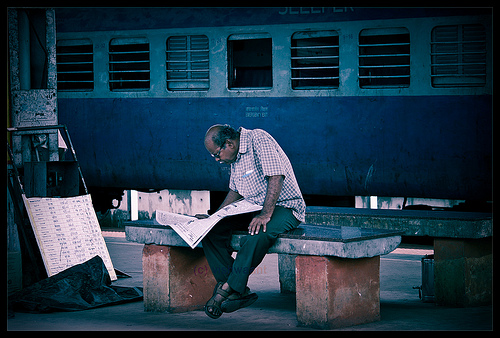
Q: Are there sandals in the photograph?
A: Yes, there are sandals.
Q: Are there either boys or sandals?
A: Yes, there are sandals.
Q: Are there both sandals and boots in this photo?
A: No, there are sandals but no boots.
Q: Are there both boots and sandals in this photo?
A: No, there are sandals but no boots.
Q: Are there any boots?
A: No, there are no boots.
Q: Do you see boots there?
A: No, there are no boots.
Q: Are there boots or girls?
A: No, there are no boots or girls.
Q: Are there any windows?
A: Yes, there is a window.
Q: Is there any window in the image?
A: Yes, there is a window.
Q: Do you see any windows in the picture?
A: Yes, there is a window.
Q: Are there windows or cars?
A: Yes, there is a window.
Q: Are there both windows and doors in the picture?
A: No, there is a window but no doors.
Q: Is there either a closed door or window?
A: Yes, there is a closed window.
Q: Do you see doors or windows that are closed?
A: Yes, the window is closed.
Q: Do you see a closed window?
A: Yes, there is a closed window.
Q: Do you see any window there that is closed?
A: Yes, there is a window that is closed.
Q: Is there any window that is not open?
A: Yes, there is an closed window.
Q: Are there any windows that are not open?
A: Yes, there is an closed window.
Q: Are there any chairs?
A: No, there are no chairs.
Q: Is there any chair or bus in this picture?
A: No, there are no chairs or buses.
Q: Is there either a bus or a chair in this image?
A: No, there are no chairs or buses.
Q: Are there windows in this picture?
A: Yes, there is a window.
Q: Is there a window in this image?
A: Yes, there is a window.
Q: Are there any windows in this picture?
A: Yes, there is a window.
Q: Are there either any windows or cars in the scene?
A: Yes, there is a window.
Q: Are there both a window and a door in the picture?
A: No, there is a window but no doors.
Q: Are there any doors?
A: No, there are no doors.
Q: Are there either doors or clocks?
A: No, there are no doors or clocks.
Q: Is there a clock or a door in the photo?
A: No, there are no doors or clocks.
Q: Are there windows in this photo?
A: Yes, there is a window.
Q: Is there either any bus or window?
A: Yes, there is a window.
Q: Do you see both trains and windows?
A: Yes, there are both a window and a train.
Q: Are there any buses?
A: No, there are no buses.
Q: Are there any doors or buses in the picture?
A: No, there are no buses or doors.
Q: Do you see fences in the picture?
A: No, there are no fences.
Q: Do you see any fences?
A: No, there are no fences.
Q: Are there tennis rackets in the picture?
A: No, there are no tennis rackets.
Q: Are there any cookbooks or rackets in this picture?
A: No, there are no rackets or cookbooks.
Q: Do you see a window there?
A: Yes, there is a window.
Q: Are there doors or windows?
A: Yes, there is a window.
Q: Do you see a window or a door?
A: Yes, there is a window.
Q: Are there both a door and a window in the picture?
A: No, there is a window but no doors.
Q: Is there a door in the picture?
A: No, there are no doors.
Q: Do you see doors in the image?
A: No, there are no doors.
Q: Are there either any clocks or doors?
A: No, there are no doors or clocks.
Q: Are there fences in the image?
A: No, there are no fences.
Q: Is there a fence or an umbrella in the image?
A: No, there are no fences or umbrellas.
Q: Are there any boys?
A: No, there are no boys.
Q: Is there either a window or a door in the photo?
A: Yes, there is a window.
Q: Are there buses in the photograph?
A: No, there are no buses.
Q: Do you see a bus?
A: No, there are no buses.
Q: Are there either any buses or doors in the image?
A: No, there are no buses or doors.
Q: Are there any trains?
A: Yes, there is a train.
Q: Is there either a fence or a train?
A: Yes, there is a train.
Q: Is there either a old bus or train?
A: Yes, there is an old train.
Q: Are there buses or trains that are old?
A: Yes, the train is old.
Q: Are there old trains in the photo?
A: Yes, there is an old train.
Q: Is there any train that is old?
A: Yes, there is a train that is old.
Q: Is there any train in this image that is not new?
A: Yes, there is a old train.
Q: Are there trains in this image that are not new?
A: Yes, there is a old train.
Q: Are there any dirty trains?
A: Yes, there is a dirty train.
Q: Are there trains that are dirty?
A: Yes, there is a train that is dirty.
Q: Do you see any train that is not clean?
A: Yes, there is a dirty train.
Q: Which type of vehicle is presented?
A: The vehicle is a train.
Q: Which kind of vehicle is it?
A: The vehicle is a train.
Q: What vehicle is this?
A: This is a train.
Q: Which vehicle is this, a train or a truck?
A: This is a train.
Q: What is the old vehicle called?
A: The vehicle is a train.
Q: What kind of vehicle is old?
A: The vehicle is a train.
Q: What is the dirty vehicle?
A: The vehicle is a train.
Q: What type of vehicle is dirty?
A: The vehicle is a train.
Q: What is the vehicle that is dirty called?
A: The vehicle is a train.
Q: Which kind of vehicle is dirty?
A: The vehicle is a train.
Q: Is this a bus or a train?
A: This is a train.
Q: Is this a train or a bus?
A: This is a train.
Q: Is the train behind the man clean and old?
A: No, the train is old but dirty.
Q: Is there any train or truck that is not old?
A: No, there is a train but it is old.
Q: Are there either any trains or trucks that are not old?
A: No, there is a train but it is old.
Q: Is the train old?
A: Yes, the train is old.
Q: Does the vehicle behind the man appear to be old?
A: Yes, the train is old.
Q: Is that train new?
A: No, the train is old.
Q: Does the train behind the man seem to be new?
A: No, the train is old.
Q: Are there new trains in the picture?
A: No, there is a train but it is old.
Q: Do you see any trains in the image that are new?
A: No, there is a train but it is old.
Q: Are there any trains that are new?
A: No, there is a train but it is old.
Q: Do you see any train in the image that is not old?
A: No, there is a train but it is old.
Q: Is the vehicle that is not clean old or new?
A: The train is old.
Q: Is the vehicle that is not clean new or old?
A: The train is old.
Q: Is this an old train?
A: Yes, this is an old train.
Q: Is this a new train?
A: No, this is an old train.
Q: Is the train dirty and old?
A: Yes, the train is dirty and old.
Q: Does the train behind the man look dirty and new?
A: No, the train is dirty but old.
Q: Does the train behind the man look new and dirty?
A: No, the train is dirty but old.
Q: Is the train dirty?
A: Yes, the train is dirty.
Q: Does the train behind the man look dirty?
A: Yes, the train is dirty.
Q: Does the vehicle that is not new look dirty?
A: Yes, the train is dirty.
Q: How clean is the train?
A: The train is dirty.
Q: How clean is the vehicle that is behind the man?
A: The train is dirty.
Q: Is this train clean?
A: No, the train is dirty.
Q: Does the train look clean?
A: No, the train is dirty.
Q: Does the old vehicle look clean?
A: No, the train is dirty.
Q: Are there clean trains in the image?
A: No, there is a train but it is dirty.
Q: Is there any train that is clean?
A: No, there is a train but it is dirty.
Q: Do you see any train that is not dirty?
A: No, there is a train but it is dirty.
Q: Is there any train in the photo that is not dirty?
A: No, there is a train but it is dirty.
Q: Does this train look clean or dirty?
A: The train is dirty.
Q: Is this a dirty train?
A: Yes, this is a dirty train.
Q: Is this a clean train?
A: No, this is a dirty train.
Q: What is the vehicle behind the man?
A: The vehicle is a train.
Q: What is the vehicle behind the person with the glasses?
A: The vehicle is a train.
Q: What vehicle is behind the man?
A: The vehicle is a train.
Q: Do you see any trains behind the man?
A: Yes, there is a train behind the man.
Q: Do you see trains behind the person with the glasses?
A: Yes, there is a train behind the man.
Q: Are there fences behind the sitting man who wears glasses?
A: No, there is a train behind the man.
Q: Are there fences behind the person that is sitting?
A: No, there is a train behind the man.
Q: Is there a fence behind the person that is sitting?
A: No, there is a train behind the man.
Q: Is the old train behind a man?
A: Yes, the train is behind a man.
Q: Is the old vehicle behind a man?
A: Yes, the train is behind a man.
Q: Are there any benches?
A: Yes, there is a bench.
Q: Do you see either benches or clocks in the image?
A: Yes, there is a bench.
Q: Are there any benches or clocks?
A: Yes, there is a bench.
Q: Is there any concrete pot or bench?
A: Yes, there is a concrete bench.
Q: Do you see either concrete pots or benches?
A: Yes, there is a concrete bench.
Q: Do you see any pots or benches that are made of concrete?
A: Yes, the bench is made of concrete.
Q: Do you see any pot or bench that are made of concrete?
A: Yes, the bench is made of concrete.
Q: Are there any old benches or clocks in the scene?
A: Yes, there is an old bench.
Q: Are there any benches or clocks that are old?
A: Yes, the bench is old.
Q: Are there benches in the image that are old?
A: Yes, there is an old bench.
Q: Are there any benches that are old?
A: Yes, there is a bench that is old.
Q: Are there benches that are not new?
A: Yes, there is a old bench.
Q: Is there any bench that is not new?
A: Yes, there is a old bench.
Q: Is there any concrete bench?
A: Yes, there is a bench that is made of concrete.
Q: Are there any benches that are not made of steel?
A: Yes, there is a bench that is made of concrete.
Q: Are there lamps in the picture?
A: No, there are no lamps.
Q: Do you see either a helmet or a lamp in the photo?
A: No, there are no lamps or helmets.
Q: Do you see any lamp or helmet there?
A: No, there are no lamps or helmets.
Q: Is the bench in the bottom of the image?
A: Yes, the bench is in the bottom of the image.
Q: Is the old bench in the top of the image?
A: No, the bench is in the bottom of the image.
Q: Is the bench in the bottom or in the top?
A: The bench is in the bottom of the image.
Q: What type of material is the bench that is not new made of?
A: The bench is made of cement.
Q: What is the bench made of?
A: The bench is made of concrete.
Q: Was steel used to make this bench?
A: No, the bench is made of cement.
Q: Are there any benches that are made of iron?
A: No, there is a bench but it is made of concrete.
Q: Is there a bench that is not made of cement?
A: No, there is a bench but it is made of cement.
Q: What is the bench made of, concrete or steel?
A: The bench is made of concrete.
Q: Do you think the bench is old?
A: Yes, the bench is old.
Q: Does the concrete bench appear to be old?
A: Yes, the bench is old.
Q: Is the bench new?
A: No, the bench is old.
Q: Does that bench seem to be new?
A: No, the bench is old.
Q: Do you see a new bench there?
A: No, there is a bench but it is old.